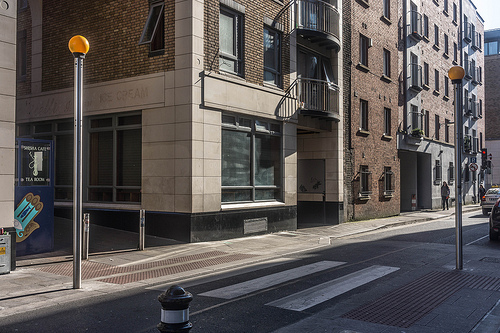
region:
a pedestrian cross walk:
[42, 232, 476, 316]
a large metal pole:
[57, 27, 93, 309]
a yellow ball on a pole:
[62, 31, 99, 64]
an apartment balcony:
[286, 47, 348, 124]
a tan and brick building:
[37, 12, 347, 246]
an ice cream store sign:
[28, 69, 175, 144]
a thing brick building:
[348, 4, 413, 233]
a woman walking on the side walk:
[434, 175, 450, 210]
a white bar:
[474, 179, 492, 213]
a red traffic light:
[479, 142, 492, 174]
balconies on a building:
[293, 2, 374, 138]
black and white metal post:
[145, 280, 219, 329]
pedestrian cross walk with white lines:
[163, 248, 403, 296]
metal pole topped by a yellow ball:
[58, 26, 107, 293]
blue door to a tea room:
[16, 137, 68, 269]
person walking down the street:
[436, 177, 458, 219]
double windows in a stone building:
[218, 126, 295, 215]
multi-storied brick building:
[348, 7, 403, 217]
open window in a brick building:
[139, 4, 180, 66]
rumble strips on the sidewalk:
[347, 280, 444, 320]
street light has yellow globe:
[439, 64, 480, 262]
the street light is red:
[475, 132, 498, 181]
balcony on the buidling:
[295, 43, 369, 120]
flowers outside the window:
[406, 124, 447, 153]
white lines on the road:
[195, 252, 400, 331]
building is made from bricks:
[336, 41, 432, 177]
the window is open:
[130, 14, 184, 65]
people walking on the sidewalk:
[420, 175, 495, 220]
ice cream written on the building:
[90, 80, 160, 108]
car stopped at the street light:
[475, 183, 498, 226]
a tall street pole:
[52, 27, 104, 296]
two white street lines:
[165, 260, 418, 331]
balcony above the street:
[284, 56, 349, 120]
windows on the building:
[207, 7, 323, 114]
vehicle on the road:
[475, 177, 499, 202]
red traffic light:
[478, 145, 498, 172]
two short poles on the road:
[75, 206, 172, 261]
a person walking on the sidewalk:
[430, 177, 468, 234]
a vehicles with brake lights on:
[472, 175, 497, 217]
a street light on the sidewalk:
[432, 59, 474, 282]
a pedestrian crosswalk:
[89, 253, 473, 318]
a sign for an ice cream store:
[12, 63, 167, 128]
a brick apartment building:
[332, 0, 404, 221]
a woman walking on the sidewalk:
[435, 180, 455, 215]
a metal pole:
[62, 29, 97, 294]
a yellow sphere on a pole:
[61, 31, 98, 59]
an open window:
[140, 5, 169, 70]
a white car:
[476, 181, 498, 216]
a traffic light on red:
[475, 145, 489, 170]